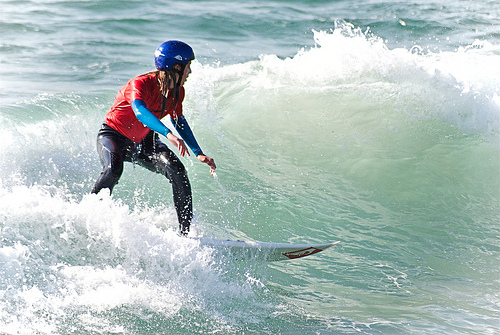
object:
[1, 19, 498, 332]
wave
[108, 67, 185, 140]
t-shirt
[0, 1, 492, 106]
water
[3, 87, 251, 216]
water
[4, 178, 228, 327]
water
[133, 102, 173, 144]
sleeve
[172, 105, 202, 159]
sleeve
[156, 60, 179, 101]
hair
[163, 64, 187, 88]
strap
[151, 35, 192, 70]
helmet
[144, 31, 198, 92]
head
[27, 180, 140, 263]
waves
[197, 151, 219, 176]
hand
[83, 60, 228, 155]
shirt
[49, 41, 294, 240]
woman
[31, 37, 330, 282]
surfer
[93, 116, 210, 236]
black pants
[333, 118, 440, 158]
waves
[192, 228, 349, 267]
surfboard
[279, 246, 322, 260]
logo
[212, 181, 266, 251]
water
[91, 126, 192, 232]
pants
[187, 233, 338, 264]
board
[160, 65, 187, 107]
sticks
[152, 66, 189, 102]
neck